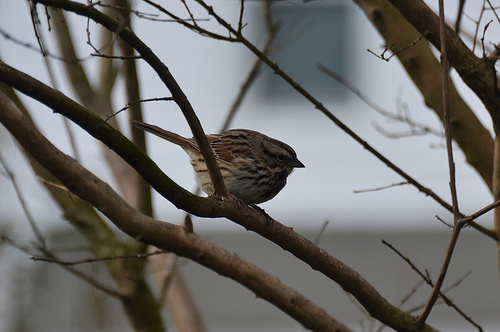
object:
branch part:
[195, 195, 290, 251]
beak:
[290, 158, 305, 169]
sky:
[6, 0, 490, 331]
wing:
[209, 133, 260, 168]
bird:
[127, 118, 305, 227]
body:
[184, 128, 286, 202]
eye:
[275, 153, 286, 163]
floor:
[0, 217, 500, 332]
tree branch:
[2, 0, 249, 330]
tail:
[127, 116, 191, 152]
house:
[0, 0, 500, 232]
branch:
[0, 0, 500, 330]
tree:
[0, 0, 500, 332]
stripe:
[217, 133, 257, 174]